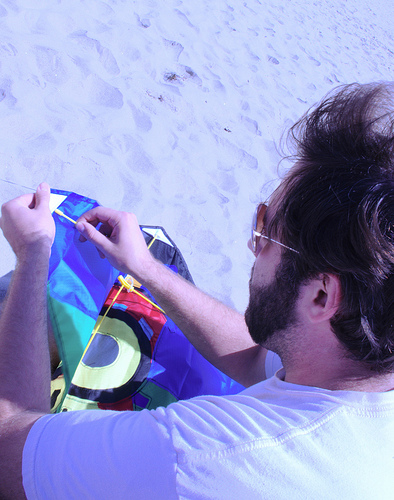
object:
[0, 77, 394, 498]
man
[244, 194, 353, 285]
glasses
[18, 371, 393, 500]
shirt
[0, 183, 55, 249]
hands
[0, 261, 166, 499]
arms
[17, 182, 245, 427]
kite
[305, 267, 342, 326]
ear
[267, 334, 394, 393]
neck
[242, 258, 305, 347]
beard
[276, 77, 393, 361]
hair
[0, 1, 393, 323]
sand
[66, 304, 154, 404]
logo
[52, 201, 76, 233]
piece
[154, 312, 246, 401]
blue